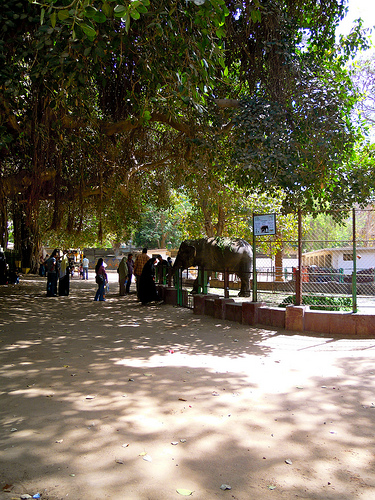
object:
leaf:
[283, 455, 292, 465]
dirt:
[17, 396, 25, 404]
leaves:
[320, 384, 330, 387]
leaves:
[68, 371, 78, 377]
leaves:
[166, 348, 176, 353]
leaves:
[77, 353, 87, 357]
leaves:
[121, 442, 129, 447]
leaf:
[124, 376, 137, 385]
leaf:
[82, 393, 93, 401]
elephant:
[166, 239, 249, 295]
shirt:
[94, 265, 109, 282]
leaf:
[179, 437, 187, 441]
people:
[140, 253, 157, 305]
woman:
[94, 257, 107, 302]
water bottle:
[104, 282, 109, 293]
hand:
[103, 278, 108, 283]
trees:
[179, 44, 233, 250]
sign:
[252, 212, 278, 236]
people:
[156, 247, 170, 285]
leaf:
[175, 486, 195, 496]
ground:
[1, 270, 373, 497]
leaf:
[290, 384, 309, 392]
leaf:
[280, 454, 291, 472]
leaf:
[118, 437, 132, 450]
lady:
[87, 255, 114, 303]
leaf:
[120, 441, 131, 447]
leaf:
[8, 424, 19, 432]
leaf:
[218, 480, 234, 490]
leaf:
[53, 438, 66, 443]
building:
[259, 240, 374, 286]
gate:
[174, 268, 209, 311]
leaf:
[169, 438, 181, 444]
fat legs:
[239, 275, 250, 297]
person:
[117, 256, 128, 294]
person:
[127, 252, 134, 293]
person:
[133, 248, 150, 283]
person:
[140, 253, 155, 305]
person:
[156, 254, 170, 282]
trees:
[136, 161, 195, 257]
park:
[2, 1, 373, 498]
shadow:
[5, 341, 375, 446]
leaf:
[78, 22, 98, 39]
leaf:
[130, 6, 141, 20]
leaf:
[342, 220, 348, 228]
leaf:
[37, 4, 45, 24]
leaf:
[57, 9, 72, 19]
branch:
[140, 98, 253, 140]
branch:
[67, 181, 77, 203]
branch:
[59, 0, 83, 26]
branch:
[1, 104, 24, 141]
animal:
[170, 237, 253, 299]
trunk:
[158, 256, 179, 285]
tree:
[0, 2, 372, 311]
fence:
[249, 210, 373, 334]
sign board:
[250, 213, 277, 238]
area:
[4, 191, 372, 496]